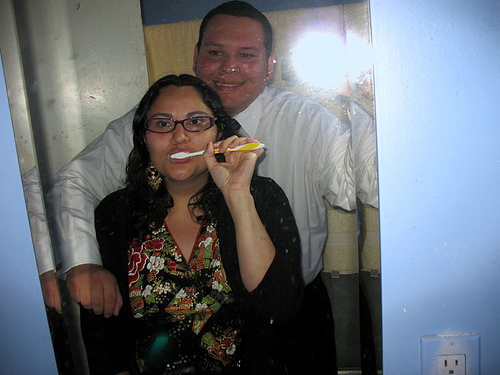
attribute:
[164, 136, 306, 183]
toothbrush — white, yellow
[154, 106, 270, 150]
glasses — rimmed, black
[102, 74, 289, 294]
lady — brushing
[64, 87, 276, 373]
lady — holding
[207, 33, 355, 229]
man — behind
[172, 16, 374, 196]
man — smiling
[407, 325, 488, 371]
plate — electrical outlet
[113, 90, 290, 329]
lady — wearing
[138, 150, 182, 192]
earring — gold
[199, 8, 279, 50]
hair — very short dark 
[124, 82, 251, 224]
hair —  long dark brown 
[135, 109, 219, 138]
glasses — dark rim 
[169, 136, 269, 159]
toothbrush — white , yellow 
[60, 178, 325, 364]
sweater — black 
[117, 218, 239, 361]
shirt — floral 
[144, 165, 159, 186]
earrings —  long gold 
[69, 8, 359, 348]
camera — reflection 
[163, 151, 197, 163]
teeth — her 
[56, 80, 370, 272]
shirt — white dress 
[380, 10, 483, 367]
wall — blue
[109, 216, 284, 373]
dress — over 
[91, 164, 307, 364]
jacket — black 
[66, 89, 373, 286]
shirt — white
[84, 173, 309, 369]
sweater — black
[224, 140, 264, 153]
stripe — yellow 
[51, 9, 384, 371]
man — very large smile, smiling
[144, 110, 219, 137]
glasses — black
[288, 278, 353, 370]
pants — black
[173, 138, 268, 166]
toothbrush — Yellow 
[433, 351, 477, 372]
outlet — electrical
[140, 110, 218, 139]
glasses — woman's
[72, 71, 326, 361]
woman — teeth-brushing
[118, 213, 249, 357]
shirt — flowered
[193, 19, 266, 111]
face — smiling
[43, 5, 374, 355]
picture — selfie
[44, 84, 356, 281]
shirt — long sleeve dress 